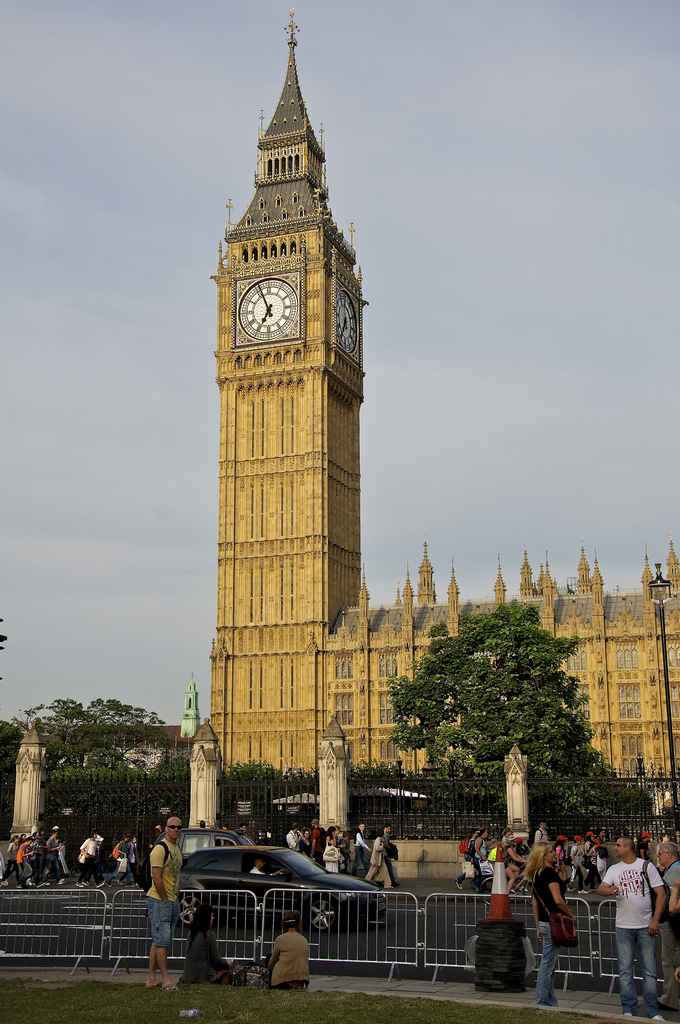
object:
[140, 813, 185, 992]
man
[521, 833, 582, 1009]
woman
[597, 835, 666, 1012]
man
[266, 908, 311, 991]
man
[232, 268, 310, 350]
clock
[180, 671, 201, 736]
church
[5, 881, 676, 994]
fence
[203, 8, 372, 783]
tower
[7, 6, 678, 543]
sky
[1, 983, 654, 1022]
grass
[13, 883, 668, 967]
road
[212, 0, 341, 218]
steeple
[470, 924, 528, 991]
can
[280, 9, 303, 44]
direction pointer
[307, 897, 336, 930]
front tire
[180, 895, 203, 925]
back tire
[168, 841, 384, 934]
car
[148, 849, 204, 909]
yellow shirt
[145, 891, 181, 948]
shorts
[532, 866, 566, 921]
shirt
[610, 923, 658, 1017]
jeans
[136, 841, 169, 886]
backpack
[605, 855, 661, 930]
t-shirt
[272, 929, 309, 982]
jacket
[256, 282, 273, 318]
dials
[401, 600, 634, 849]
tree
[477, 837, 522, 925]
cone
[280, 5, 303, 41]
weather vane